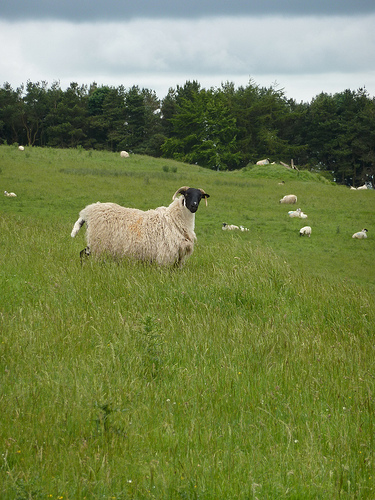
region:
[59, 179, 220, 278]
THIS IS A SHEEP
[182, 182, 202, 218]
THE SHEEP HAS A BLACK FACE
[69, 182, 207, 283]
THE SHEEP HAS WHITE WOOL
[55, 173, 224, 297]
THE SHEEP IS FLUFFY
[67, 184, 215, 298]
THE SHEEP IS WOOLY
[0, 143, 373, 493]
THE GRASS IS GREEN AND HIGH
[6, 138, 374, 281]
MANY SHEEP DOT THE HILLSIDE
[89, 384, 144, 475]
THIS IS A WEED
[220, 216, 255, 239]
THE SHEEP IS LYING DOWN IN THE GRASS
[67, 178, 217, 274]
THE SHEEP IS STANDING IN THE TALL GRASS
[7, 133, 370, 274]
A field full of grazing sheep.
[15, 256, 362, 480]
Green grass in the meadow.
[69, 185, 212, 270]
Sheep with black head.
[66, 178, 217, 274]
Sheep with turned down horns.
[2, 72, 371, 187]
Green trees in the background.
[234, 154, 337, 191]
Two sheep on a hill.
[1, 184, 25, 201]
A little white lamb.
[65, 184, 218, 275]
Lots of wool for shearing.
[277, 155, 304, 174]
Old wooden fence posts.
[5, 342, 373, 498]
Tall green grass with yellow flowers.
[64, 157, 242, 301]
old sheep standing in grass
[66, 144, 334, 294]
sheep grazing in grassy field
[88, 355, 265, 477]
tall grass in field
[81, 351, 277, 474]
tall green grass in field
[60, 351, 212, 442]
field of tall green grass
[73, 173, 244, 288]
sheep with long horns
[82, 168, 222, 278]
sheep with white fur and black face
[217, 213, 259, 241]
sheep laying down in grass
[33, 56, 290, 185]
tall trees behind field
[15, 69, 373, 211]
tall trees in background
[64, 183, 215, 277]
sheep standing in the grass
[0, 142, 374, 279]
fiveteen sheep in the shot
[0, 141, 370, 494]
the grass is green and hilly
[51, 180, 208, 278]
the shep is white,brown,black and tan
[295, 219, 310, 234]
the sheep is eating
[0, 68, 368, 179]
the trees leaves are green and dark green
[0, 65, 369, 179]
the trees are brown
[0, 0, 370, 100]
the sky is white and cloudy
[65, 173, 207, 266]
the sheep is faceing the camera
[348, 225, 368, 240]
the sheep is faceing away from the camera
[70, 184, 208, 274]
a sheep in a field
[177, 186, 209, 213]
black head of a sheep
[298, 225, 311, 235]
a sheep in the distance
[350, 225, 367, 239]
a sheep in a field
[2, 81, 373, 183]
a patch of tall trees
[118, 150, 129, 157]
a sheep in the distance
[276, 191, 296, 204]
a sheep in the field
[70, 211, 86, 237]
a sheep's tail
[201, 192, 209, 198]
the ear of a sheep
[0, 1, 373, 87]
a cloudy blue sky